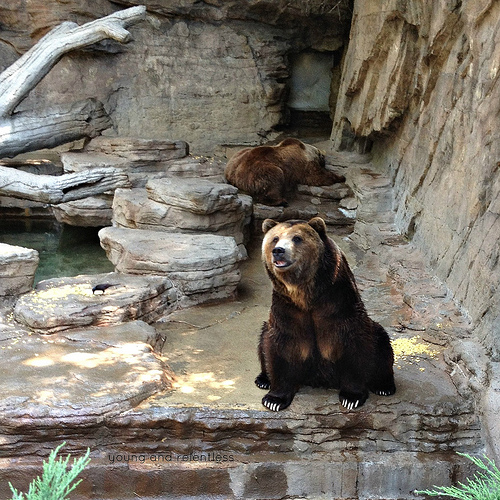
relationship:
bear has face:
[245, 217, 398, 411] [267, 229, 314, 281]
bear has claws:
[245, 217, 398, 411] [341, 397, 363, 411]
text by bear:
[106, 452, 236, 463] [245, 217, 398, 411]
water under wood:
[0, 217, 118, 285] [0, 4, 149, 204]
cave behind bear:
[291, 46, 336, 134] [224, 137, 346, 205]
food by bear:
[389, 335, 439, 362] [245, 217, 398, 411]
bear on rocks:
[245, 217, 398, 411] [0, 138, 499, 499]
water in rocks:
[0, 217, 118, 285] [0, 138, 499, 499]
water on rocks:
[0, 217, 118, 285] [0, 138, 499, 499]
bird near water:
[91, 282, 121, 294] [0, 217, 118, 285]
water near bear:
[0, 217, 118, 285] [245, 217, 398, 411]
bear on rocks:
[224, 137, 346, 205] [0, 138, 499, 499]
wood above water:
[0, 4, 149, 204] [0, 217, 118, 285]